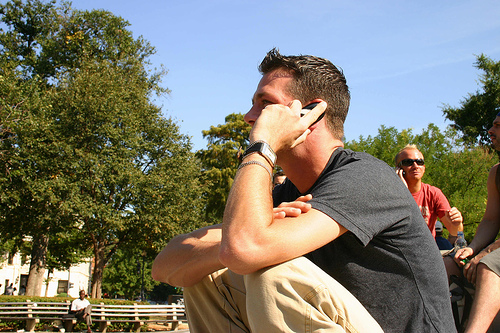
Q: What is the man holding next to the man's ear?
A: His phone.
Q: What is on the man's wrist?
A: A watch.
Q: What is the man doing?
A: Talking on his phone.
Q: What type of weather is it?
A: Sunny.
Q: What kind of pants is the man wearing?
A: Khakis.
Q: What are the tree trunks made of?
A: Wood.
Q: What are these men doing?
A: Talking on phones.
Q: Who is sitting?
A: The man with a grey shirt.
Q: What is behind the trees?
A: A white building.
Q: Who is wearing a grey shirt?
A: A man with brown hair.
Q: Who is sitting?
A: A man talking on the phone.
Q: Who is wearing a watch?
A: The man on the phone.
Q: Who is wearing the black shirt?
A: A man.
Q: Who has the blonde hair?
A: A man wearing shades.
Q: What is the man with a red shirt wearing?
A: Sunglasses.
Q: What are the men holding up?
A: Phones.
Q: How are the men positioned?
A: Sitting.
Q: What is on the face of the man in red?
A: Sunglasses.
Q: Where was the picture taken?
A: In a park.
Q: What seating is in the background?
A: Benches.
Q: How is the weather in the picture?
A: Sunny.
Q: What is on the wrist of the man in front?
A: A watch.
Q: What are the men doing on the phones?
A: Talking.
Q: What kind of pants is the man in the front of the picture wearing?
A: Khaki.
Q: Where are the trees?
A: Background.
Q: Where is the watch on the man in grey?
A: Left hand.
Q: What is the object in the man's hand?
A: A cell phone.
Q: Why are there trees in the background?
A: Trees surround the area.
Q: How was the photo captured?
A: With a camera.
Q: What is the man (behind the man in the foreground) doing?
A: Talking on a cell phone.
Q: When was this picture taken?
A: Daytime.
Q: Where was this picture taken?
A: In the park.